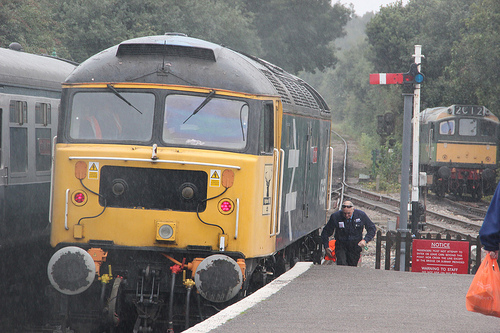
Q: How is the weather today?
A: It is cloudy.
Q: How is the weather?
A: It is cloudy.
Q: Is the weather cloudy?
A: Yes, it is cloudy.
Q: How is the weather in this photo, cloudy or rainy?
A: It is cloudy.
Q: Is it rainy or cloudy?
A: It is cloudy.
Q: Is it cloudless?
A: No, it is cloudy.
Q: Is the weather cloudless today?
A: No, it is cloudy.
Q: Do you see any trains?
A: Yes, there is a train.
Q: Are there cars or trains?
A: Yes, there is a train.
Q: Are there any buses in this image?
A: No, there are no buses.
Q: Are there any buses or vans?
A: No, there are no buses or vans.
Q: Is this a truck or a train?
A: This is a train.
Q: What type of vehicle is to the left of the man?
A: The vehicle is a train.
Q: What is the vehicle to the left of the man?
A: The vehicle is a train.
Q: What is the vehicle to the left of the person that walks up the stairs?
A: The vehicle is a train.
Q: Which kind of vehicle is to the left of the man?
A: The vehicle is a train.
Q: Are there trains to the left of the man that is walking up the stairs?
A: Yes, there is a train to the left of the man.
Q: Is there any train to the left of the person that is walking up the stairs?
A: Yes, there is a train to the left of the man.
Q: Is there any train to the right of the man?
A: No, the train is to the left of the man.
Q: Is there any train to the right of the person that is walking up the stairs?
A: No, the train is to the left of the man.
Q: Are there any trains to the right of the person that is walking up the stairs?
A: No, the train is to the left of the man.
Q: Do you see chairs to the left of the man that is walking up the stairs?
A: No, there is a train to the left of the man.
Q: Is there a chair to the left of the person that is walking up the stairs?
A: No, there is a train to the left of the man.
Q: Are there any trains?
A: Yes, there is a train.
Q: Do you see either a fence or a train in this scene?
A: Yes, there is a train.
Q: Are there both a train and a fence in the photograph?
A: Yes, there are both a train and a fence.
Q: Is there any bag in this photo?
A: Yes, there is a bag.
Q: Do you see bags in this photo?
A: Yes, there is a bag.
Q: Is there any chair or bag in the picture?
A: Yes, there is a bag.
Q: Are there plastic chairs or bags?
A: Yes, there is a plastic bag.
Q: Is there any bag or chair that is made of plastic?
A: Yes, the bag is made of plastic.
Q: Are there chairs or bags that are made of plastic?
A: Yes, the bag is made of plastic.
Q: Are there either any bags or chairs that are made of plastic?
A: Yes, the bag is made of plastic.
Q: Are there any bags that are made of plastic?
A: Yes, there is a bag that is made of plastic.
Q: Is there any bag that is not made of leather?
A: Yes, there is a bag that is made of plastic.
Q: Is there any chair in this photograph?
A: No, there are no chairs.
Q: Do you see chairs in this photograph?
A: No, there are no chairs.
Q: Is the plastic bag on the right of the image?
A: Yes, the bag is on the right of the image.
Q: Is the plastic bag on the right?
A: Yes, the bag is on the right of the image.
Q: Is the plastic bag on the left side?
A: No, the bag is on the right of the image.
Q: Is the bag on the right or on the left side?
A: The bag is on the right of the image.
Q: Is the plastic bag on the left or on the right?
A: The bag is on the right of the image.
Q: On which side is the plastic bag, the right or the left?
A: The bag is on the right of the image.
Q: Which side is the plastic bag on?
A: The bag is on the right of the image.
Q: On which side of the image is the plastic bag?
A: The bag is on the right of the image.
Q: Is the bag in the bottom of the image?
A: Yes, the bag is in the bottom of the image.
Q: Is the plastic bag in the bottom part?
A: Yes, the bag is in the bottom of the image.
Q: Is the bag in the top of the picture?
A: No, the bag is in the bottom of the image.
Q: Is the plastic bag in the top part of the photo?
A: No, the bag is in the bottom of the image.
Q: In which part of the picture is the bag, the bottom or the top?
A: The bag is in the bottom of the image.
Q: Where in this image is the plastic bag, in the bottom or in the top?
A: The bag is in the bottom of the image.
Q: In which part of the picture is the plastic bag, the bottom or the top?
A: The bag is in the bottom of the image.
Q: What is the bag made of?
A: The bag is made of plastic.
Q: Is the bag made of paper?
A: No, the bag is made of plastic.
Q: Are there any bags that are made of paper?
A: No, there is a bag but it is made of plastic.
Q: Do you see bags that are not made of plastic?
A: No, there is a bag but it is made of plastic.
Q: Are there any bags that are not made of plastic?
A: No, there is a bag but it is made of plastic.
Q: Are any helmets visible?
A: No, there are no helmets.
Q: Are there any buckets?
A: No, there are no buckets.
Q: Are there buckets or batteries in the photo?
A: No, there are no buckets or batteries.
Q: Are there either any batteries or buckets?
A: No, there are no buckets or batteries.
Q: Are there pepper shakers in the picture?
A: No, there are no pepper shakers.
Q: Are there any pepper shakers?
A: No, there are no pepper shakers.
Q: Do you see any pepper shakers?
A: No, there are no pepper shakers.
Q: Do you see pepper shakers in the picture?
A: No, there are no pepper shakers.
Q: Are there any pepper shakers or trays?
A: No, there are no pepper shakers or trays.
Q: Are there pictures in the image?
A: No, there are no pictures.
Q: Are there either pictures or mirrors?
A: No, there are no pictures or mirrors.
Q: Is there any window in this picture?
A: Yes, there is a window.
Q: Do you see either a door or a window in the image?
A: Yes, there is a window.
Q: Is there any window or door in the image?
A: Yes, there is a window.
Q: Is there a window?
A: Yes, there is a window.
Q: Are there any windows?
A: Yes, there is a window.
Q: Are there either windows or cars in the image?
A: Yes, there is a window.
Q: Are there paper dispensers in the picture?
A: No, there are no paper dispensers.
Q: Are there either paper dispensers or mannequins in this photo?
A: No, there are no paper dispensers or mannequins.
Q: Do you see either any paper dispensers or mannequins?
A: No, there are no paper dispensers or mannequins.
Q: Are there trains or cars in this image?
A: Yes, there is a train.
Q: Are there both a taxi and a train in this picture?
A: No, there is a train but no taxis.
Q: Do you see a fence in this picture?
A: Yes, there is a fence.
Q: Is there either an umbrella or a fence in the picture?
A: Yes, there is a fence.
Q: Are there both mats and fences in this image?
A: No, there is a fence but no mats.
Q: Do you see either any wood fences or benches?
A: Yes, there is a wood fence.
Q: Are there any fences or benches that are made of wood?
A: Yes, the fence is made of wood.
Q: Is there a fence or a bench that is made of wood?
A: Yes, the fence is made of wood.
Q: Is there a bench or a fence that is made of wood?
A: Yes, the fence is made of wood.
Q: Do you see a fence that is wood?
A: Yes, there is a wood fence.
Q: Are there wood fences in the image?
A: Yes, there is a wood fence.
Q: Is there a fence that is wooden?
A: Yes, there is a fence that is wooden.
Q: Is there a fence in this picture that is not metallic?
A: Yes, there is a wooden fence.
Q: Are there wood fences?
A: Yes, there is a fence that is made of wood.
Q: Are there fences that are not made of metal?
A: Yes, there is a fence that is made of wood.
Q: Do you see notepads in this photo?
A: No, there are no notepads.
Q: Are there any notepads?
A: No, there are no notepads.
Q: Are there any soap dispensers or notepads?
A: No, there are no notepads or soap dispensers.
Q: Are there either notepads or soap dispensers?
A: No, there are no notepads or soap dispensers.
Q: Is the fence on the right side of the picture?
A: Yes, the fence is on the right of the image.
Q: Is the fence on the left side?
A: No, the fence is on the right of the image.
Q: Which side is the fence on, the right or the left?
A: The fence is on the right of the image.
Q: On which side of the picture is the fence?
A: The fence is on the right of the image.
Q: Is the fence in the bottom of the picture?
A: Yes, the fence is in the bottom of the image.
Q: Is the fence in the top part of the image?
A: No, the fence is in the bottom of the image.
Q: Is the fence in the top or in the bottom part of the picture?
A: The fence is in the bottom of the image.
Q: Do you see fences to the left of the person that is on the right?
A: Yes, there is a fence to the left of the person.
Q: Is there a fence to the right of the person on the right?
A: No, the fence is to the left of the person.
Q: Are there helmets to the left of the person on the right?
A: No, there is a fence to the left of the person.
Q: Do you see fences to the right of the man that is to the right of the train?
A: Yes, there is a fence to the right of the man.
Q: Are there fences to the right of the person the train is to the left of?
A: Yes, there is a fence to the right of the man.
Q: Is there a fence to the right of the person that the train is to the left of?
A: Yes, there is a fence to the right of the man.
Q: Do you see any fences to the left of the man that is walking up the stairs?
A: No, the fence is to the right of the man.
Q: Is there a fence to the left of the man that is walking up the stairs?
A: No, the fence is to the right of the man.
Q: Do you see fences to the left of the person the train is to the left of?
A: No, the fence is to the right of the man.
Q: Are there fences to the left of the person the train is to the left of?
A: No, the fence is to the right of the man.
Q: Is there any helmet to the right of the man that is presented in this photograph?
A: No, there is a fence to the right of the man.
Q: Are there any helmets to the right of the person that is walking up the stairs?
A: No, there is a fence to the right of the man.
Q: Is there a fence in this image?
A: Yes, there is a fence.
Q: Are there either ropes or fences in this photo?
A: Yes, there is a fence.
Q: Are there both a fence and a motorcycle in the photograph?
A: No, there is a fence but no motorcycles.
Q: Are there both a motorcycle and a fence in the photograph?
A: No, there is a fence but no motorcycles.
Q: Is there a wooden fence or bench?
A: Yes, there is a wood fence.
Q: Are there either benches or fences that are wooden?
A: Yes, the fence is wooden.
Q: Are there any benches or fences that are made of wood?
A: Yes, the fence is made of wood.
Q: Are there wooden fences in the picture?
A: Yes, there is a wood fence.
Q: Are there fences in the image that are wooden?
A: Yes, there is a fence that is wooden.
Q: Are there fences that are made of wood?
A: Yes, there is a fence that is made of wood.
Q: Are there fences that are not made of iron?
A: Yes, there is a fence that is made of wood.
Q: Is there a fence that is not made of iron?
A: Yes, there is a fence that is made of wood.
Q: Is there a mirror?
A: No, there are no mirrors.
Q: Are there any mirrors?
A: No, there are no mirrors.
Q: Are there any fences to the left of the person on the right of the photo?
A: Yes, there is a fence to the left of the person.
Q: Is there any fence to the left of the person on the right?
A: Yes, there is a fence to the left of the person.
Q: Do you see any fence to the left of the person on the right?
A: Yes, there is a fence to the left of the person.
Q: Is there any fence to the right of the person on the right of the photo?
A: No, the fence is to the left of the person.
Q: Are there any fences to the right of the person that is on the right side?
A: No, the fence is to the left of the person.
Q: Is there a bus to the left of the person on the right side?
A: No, there is a fence to the left of the person.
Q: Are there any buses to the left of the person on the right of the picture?
A: No, there is a fence to the left of the person.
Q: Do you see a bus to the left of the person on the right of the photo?
A: No, there is a fence to the left of the person.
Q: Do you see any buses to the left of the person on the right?
A: No, there is a fence to the left of the person.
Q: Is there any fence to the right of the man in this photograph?
A: Yes, there is a fence to the right of the man.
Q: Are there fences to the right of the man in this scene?
A: Yes, there is a fence to the right of the man.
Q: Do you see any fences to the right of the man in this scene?
A: Yes, there is a fence to the right of the man.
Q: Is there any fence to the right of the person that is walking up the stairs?
A: Yes, there is a fence to the right of the man.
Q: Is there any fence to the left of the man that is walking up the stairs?
A: No, the fence is to the right of the man.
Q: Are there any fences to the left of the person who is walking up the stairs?
A: No, the fence is to the right of the man.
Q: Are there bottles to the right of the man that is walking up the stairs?
A: No, there is a fence to the right of the man.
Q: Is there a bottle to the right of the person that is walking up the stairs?
A: No, there is a fence to the right of the man.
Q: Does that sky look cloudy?
A: Yes, the sky is cloudy.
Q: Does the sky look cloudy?
A: Yes, the sky is cloudy.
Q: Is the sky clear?
A: No, the sky is cloudy.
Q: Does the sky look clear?
A: No, the sky is cloudy.